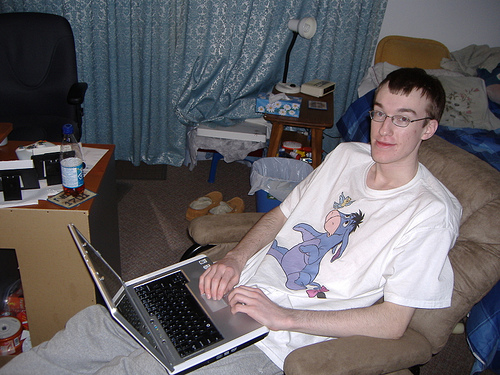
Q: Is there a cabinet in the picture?
A: No, there are no cabinets.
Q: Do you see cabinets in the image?
A: No, there are no cabinets.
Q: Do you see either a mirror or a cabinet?
A: No, there are no cabinets or mirrors.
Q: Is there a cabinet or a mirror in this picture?
A: No, there are no cabinets or mirrors.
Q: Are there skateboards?
A: No, there are no skateboards.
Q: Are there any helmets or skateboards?
A: No, there are no skateboards or helmets.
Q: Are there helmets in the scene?
A: No, there are no helmets.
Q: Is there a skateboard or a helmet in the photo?
A: No, there are no helmets or skateboards.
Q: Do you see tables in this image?
A: Yes, there is a table.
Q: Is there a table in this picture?
A: Yes, there is a table.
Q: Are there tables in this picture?
A: Yes, there is a table.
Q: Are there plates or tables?
A: Yes, there is a table.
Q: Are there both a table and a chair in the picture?
A: Yes, there are both a table and a chair.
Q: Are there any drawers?
A: No, there are no drawers.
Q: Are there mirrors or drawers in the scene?
A: No, there are no drawers or mirrors.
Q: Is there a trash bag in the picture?
A: Yes, there is a trash bag.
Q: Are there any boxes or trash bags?
A: Yes, there is a trash bag.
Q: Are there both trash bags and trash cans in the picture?
A: Yes, there are both a trash bag and a trash can.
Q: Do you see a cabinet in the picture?
A: No, there are no cabinets.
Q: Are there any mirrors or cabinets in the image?
A: No, there are no cabinets or mirrors.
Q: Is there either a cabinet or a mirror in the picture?
A: No, there are no cabinets or mirrors.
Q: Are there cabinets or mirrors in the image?
A: No, there are no cabinets or mirrors.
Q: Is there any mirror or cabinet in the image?
A: No, there are no cabinets or mirrors.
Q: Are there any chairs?
A: Yes, there is a chair.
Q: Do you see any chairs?
A: Yes, there is a chair.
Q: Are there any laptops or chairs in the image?
A: Yes, there is a chair.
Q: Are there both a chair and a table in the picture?
A: Yes, there are both a chair and a table.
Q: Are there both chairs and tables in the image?
A: Yes, there are both a chair and a table.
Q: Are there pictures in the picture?
A: No, there are no pictures.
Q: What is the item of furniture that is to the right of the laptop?
A: The piece of furniture is a chair.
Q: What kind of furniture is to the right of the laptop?
A: The piece of furniture is a chair.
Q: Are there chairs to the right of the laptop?
A: Yes, there is a chair to the right of the laptop.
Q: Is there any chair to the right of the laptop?
A: Yes, there is a chair to the right of the laptop.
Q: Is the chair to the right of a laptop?
A: Yes, the chair is to the right of a laptop.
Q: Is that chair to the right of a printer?
A: No, the chair is to the right of a laptop.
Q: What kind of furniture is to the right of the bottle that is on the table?
A: The piece of furniture is a chair.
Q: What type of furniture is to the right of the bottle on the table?
A: The piece of furniture is a chair.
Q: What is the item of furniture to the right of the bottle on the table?
A: The piece of furniture is a chair.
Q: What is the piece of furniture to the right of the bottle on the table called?
A: The piece of furniture is a chair.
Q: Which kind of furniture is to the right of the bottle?
A: The piece of furniture is a chair.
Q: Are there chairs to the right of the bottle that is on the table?
A: Yes, there is a chair to the right of the bottle.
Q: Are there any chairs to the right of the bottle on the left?
A: Yes, there is a chair to the right of the bottle.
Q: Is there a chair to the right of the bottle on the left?
A: Yes, there is a chair to the right of the bottle.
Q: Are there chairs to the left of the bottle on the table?
A: No, the chair is to the right of the bottle.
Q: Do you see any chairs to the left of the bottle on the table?
A: No, the chair is to the right of the bottle.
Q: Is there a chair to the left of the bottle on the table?
A: No, the chair is to the right of the bottle.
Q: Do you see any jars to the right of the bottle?
A: No, there is a chair to the right of the bottle.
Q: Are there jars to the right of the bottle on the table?
A: No, there is a chair to the right of the bottle.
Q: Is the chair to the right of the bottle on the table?
A: Yes, the chair is to the right of the bottle.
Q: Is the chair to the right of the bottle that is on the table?
A: Yes, the chair is to the right of the bottle.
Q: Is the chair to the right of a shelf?
A: No, the chair is to the right of the bottle.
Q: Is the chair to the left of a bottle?
A: No, the chair is to the right of a bottle.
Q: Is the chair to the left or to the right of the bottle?
A: The chair is to the right of the bottle.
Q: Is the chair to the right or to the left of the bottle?
A: The chair is to the right of the bottle.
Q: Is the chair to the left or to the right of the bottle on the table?
A: The chair is to the right of the bottle.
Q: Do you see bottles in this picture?
A: Yes, there is a bottle.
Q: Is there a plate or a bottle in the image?
A: Yes, there is a bottle.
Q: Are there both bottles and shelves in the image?
A: No, there is a bottle but no shelves.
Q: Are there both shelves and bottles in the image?
A: No, there is a bottle but no shelves.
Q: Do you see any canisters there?
A: No, there are no canisters.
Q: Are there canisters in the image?
A: No, there are no canisters.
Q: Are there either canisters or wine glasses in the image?
A: No, there are no canisters or wine glasses.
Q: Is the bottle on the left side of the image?
A: Yes, the bottle is on the left of the image.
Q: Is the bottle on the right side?
A: No, the bottle is on the left of the image.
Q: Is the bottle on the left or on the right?
A: The bottle is on the left of the image.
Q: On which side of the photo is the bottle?
A: The bottle is on the left of the image.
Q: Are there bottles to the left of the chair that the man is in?
A: Yes, there is a bottle to the left of the chair.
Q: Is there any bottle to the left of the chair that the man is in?
A: Yes, there is a bottle to the left of the chair.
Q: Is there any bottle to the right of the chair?
A: No, the bottle is to the left of the chair.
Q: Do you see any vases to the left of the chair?
A: No, there is a bottle to the left of the chair.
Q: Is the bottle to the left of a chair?
A: Yes, the bottle is to the left of a chair.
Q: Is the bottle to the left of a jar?
A: No, the bottle is to the left of a chair.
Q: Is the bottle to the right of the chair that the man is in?
A: No, the bottle is to the left of the chair.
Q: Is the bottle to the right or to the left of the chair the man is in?
A: The bottle is to the left of the chair.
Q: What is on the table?
A: The bottle is on the table.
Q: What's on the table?
A: The bottle is on the table.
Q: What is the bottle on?
A: The bottle is on the table.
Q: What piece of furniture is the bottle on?
A: The bottle is on the table.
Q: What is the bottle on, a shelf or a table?
A: The bottle is on a table.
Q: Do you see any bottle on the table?
A: Yes, there is a bottle on the table.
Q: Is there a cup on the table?
A: No, there is a bottle on the table.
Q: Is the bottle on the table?
A: Yes, the bottle is on the table.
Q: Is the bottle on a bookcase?
A: No, the bottle is on the table.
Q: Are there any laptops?
A: Yes, there is a laptop.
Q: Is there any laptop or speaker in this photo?
A: Yes, there is a laptop.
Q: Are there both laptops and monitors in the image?
A: No, there is a laptop but no monitors.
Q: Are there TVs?
A: No, there are no tvs.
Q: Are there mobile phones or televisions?
A: No, there are no televisions or mobile phones.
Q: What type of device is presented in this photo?
A: The device is a laptop.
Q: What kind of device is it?
A: The device is a laptop.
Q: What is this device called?
A: This is a laptop.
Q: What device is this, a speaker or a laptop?
A: This is a laptop.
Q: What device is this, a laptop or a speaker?
A: This is a laptop.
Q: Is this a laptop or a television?
A: This is a laptop.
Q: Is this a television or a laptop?
A: This is a laptop.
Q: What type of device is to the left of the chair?
A: The device is a laptop.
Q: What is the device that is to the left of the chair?
A: The device is a laptop.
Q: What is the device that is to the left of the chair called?
A: The device is a laptop.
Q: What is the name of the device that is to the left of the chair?
A: The device is a laptop.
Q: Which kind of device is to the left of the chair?
A: The device is a laptop.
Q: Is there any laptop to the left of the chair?
A: Yes, there is a laptop to the left of the chair.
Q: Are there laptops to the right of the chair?
A: No, the laptop is to the left of the chair.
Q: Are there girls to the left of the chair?
A: No, there is a laptop to the left of the chair.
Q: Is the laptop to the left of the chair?
A: Yes, the laptop is to the left of the chair.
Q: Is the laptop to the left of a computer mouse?
A: No, the laptop is to the left of the chair.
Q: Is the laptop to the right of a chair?
A: No, the laptop is to the left of a chair.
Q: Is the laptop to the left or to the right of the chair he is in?
A: The laptop is to the left of the chair.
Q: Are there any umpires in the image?
A: No, there are no umpires.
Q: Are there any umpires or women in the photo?
A: No, there are no umpires or women.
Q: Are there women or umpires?
A: No, there are no umpires or women.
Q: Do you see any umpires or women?
A: No, there are no umpires or women.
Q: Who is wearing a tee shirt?
A: The man is wearing a tee shirt.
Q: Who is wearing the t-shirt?
A: The man is wearing a tee shirt.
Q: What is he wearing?
A: The man is wearing a t-shirt.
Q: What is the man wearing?
A: The man is wearing a t-shirt.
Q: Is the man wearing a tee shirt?
A: Yes, the man is wearing a tee shirt.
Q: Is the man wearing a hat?
A: No, the man is wearing a tee shirt.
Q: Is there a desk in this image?
A: Yes, there is a desk.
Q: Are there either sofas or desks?
A: Yes, there is a desk.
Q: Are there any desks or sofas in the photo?
A: Yes, there is a desk.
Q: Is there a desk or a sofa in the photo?
A: Yes, there is a desk.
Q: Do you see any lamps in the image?
A: Yes, there is a lamp.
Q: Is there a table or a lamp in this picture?
A: Yes, there is a lamp.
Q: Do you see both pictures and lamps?
A: No, there is a lamp but no pictures.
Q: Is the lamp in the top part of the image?
A: Yes, the lamp is in the top of the image.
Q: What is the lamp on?
A: The lamp is on the desk.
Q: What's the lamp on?
A: The lamp is on the desk.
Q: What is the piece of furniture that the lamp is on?
A: The piece of furniture is a desk.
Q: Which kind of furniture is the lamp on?
A: The lamp is on the desk.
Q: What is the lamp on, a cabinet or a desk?
A: The lamp is on a desk.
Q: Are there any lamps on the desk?
A: Yes, there is a lamp on the desk.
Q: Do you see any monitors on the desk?
A: No, there is a lamp on the desk.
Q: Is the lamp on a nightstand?
A: No, the lamp is on the desk.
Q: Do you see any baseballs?
A: No, there are no baseballs.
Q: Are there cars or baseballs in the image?
A: No, there are no baseballs or cars.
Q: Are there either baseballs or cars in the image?
A: No, there are no baseballs or cars.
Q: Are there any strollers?
A: No, there are no strollers.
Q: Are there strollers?
A: No, there are no strollers.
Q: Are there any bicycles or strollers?
A: No, there are no strollers or bicycles.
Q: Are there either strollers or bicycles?
A: No, there are no strollers or bicycles.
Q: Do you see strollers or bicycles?
A: No, there are no strollers or bicycles.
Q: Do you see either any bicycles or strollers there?
A: No, there are no strollers or bicycles.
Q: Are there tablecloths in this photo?
A: No, there are no tablecloths.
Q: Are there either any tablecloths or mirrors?
A: No, there are no tablecloths or mirrors.